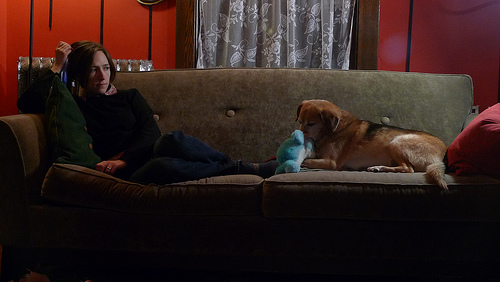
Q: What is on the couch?
A: Dog and person.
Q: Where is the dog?
A: On couch.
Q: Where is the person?
A: On couch.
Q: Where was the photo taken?
A: In a room.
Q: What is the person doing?
A: Looking at something.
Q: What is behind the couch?
A: Curtains.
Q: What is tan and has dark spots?
A: The dog.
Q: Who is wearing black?
A: The person.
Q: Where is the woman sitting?
A: On a couch.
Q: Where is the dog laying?
A: On the couch.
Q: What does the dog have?
A: A blue toy.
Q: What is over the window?
A: Curtains.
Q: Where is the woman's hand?
A: On her head.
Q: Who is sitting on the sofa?
A: A woman and dog.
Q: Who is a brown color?
A: A dog.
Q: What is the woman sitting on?
A: Sofa.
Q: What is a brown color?
A: Sofa.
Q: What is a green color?
A: A cushion.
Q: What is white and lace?
A: A curtain.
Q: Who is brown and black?
A: The dog.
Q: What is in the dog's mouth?
A: A stuffed animal.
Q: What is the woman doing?
A: Looking off in the distance.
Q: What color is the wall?
A: Red.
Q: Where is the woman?
A: On the couch.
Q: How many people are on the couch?
A: One.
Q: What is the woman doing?
A: Sitting on the couch.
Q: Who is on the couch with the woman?
A: A dog.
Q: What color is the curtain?
A: Grey and white.